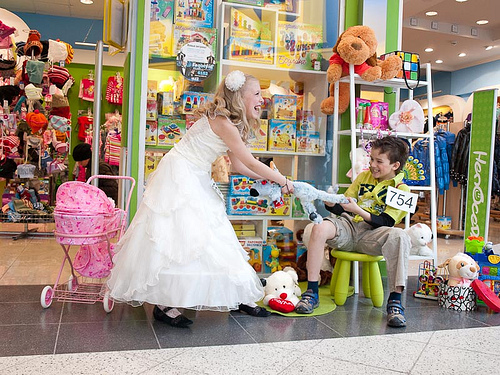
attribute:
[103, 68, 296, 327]
girl — blonde, smiling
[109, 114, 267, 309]
dress — white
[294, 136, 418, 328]
boy — sitting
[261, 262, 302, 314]
bear — white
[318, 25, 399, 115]
stuffed animal — brown, large, a dog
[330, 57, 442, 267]
shelf — white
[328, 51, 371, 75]
shirt — red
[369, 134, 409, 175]
hair — brown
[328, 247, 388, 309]
stool — green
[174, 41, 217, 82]
sign — round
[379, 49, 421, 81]
rubix cube — large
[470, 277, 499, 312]
lid — red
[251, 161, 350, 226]
toy — blue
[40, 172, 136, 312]
toy stroller — pink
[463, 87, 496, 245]
sign — green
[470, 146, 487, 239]
letters — white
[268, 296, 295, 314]
heart — red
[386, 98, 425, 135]
box — white, heart-shaped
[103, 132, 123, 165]
shirt — striped, long sleeved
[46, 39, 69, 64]
hat — hanging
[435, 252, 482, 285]
toy — tan, white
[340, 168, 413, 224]
shirt — green